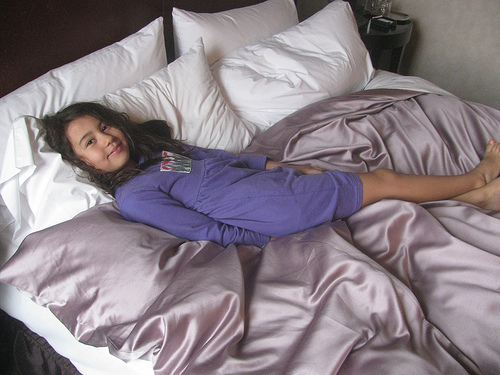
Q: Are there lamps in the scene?
A: No, there are no lamps.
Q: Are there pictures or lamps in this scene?
A: No, there are no lamps or pictures.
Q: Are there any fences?
A: No, there are no fences.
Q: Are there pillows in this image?
A: Yes, there is a pillow.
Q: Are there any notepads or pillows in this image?
A: Yes, there is a pillow.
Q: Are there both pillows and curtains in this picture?
A: No, there is a pillow but no curtains.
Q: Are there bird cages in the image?
A: No, there are no bird cages.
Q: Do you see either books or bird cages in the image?
A: No, there are no bird cages or books.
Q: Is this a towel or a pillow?
A: This is a pillow.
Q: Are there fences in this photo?
A: No, there are no fences.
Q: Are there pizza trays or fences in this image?
A: No, there are no fences or pizza trays.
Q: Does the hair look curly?
A: Yes, the hair is curly.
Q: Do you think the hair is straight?
A: No, the hair is curly.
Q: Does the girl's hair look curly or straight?
A: The hair is curly.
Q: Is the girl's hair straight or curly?
A: The hair is curly.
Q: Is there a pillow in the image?
A: Yes, there is a pillow.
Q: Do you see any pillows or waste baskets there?
A: Yes, there is a pillow.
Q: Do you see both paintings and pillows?
A: No, there is a pillow but no paintings.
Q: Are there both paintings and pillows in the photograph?
A: No, there is a pillow but no paintings.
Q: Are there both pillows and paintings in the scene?
A: No, there is a pillow but no paintings.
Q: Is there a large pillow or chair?
A: Yes, there is a large pillow.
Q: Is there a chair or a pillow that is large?
A: Yes, the pillow is large.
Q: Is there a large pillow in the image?
A: Yes, there is a large pillow.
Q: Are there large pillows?
A: Yes, there is a large pillow.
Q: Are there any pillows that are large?
A: Yes, there is a pillow that is large.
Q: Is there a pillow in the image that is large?
A: Yes, there is a pillow that is large.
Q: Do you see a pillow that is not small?
A: Yes, there is a large pillow.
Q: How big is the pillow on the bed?
A: The pillow is large.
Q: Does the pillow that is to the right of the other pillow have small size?
A: No, the pillow is large.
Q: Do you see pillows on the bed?
A: Yes, there is a pillow on the bed.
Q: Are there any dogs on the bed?
A: No, there is a pillow on the bed.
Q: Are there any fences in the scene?
A: No, there are no fences.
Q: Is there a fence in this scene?
A: No, there are no fences.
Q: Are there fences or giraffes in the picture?
A: No, there are no fences or giraffes.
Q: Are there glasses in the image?
A: No, there are no glasses.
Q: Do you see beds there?
A: Yes, there is a bed.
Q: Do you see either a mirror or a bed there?
A: Yes, there is a bed.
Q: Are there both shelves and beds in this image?
A: No, there is a bed but no shelves.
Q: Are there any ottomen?
A: No, there are no ottomen.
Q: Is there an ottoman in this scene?
A: No, there are no ottomen.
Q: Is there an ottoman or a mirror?
A: No, there are no ottomen or mirrors.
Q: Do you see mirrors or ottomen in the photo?
A: No, there are no ottomen or mirrors.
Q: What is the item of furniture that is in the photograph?
A: The piece of furniture is a bed.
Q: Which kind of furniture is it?
A: The piece of furniture is a bed.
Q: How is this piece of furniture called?
A: This is a bed.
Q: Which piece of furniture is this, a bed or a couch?
A: This is a bed.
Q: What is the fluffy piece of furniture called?
A: The piece of furniture is a bed.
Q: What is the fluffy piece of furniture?
A: The piece of furniture is a bed.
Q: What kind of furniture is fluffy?
A: The furniture is a bed.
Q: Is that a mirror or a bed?
A: That is a bed.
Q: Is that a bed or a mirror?
A: That is a bed.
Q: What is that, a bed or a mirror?
A: That is a bed.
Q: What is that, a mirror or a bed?
A: That is a bed.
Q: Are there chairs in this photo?
A: No, there are no chairs.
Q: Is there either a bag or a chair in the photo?
A: No, there are no chairs or bags.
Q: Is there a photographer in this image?
A: No, there are no photographers.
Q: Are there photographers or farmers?
A: No, there are no photographers or farmers.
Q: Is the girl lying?
A: Yes, the girl is lying.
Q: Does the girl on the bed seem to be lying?
A: Yes, the girl is lying.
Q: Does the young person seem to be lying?
A: Yes, the girl is lying.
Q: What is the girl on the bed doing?
A: The girl is lying.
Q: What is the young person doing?
A: The girl is lying.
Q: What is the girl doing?
A: The girl is lying.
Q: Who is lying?
A: The girl is lying.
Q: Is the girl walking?
A: No, the girl is lying.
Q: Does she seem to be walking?
A: No, the girl is lying.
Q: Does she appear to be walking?
A: No, the girl is lying.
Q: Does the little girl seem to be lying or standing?
A: The girl is lying.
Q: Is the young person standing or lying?
A: The girl is lying.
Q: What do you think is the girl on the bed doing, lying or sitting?
A: The girl is lying.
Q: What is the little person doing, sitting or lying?
A: The girl is lying.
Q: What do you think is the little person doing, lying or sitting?
A: The girl is lying.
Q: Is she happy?
A: Yes, the girl is happy.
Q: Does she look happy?
A: Yes, the girl is happy.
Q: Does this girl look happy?
A: Yes, the girl is happy.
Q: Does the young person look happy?
A: Yes, the girl is happy.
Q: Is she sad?
A: No, the girl is happy.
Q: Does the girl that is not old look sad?
A: No, the girl is happy.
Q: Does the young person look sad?
A: No, the girl is happy.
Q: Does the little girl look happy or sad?
A: The girl is happy.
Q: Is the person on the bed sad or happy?
A: The girl is happy.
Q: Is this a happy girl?
A: Yes, this is a happy girl.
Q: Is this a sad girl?
A: No, this is a happy girl.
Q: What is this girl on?
A: The girl is on the bed.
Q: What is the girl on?
A: The girl is on the bed.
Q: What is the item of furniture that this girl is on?
A: The piece of furniture is a bed.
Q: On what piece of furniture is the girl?
A: The girl is on the bed.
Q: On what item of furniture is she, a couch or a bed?
A: The girl is on a bed.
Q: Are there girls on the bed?
A: Yes, there is a girl on the bed.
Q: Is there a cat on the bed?
A: No, there is a girl on the bed.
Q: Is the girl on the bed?
A: Yes, the girl is on the bed.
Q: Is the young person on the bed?
A: Yes, the girl is on the bed.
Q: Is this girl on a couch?
A: No, the girl is on the bed.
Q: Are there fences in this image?
A: No, there are no fences.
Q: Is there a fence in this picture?
A: No, there are no fences.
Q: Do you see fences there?
A: No, there are no fences.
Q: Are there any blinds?
A: No, there are no blinds.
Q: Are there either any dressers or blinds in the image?
A: No, there are no blinds or dressers.